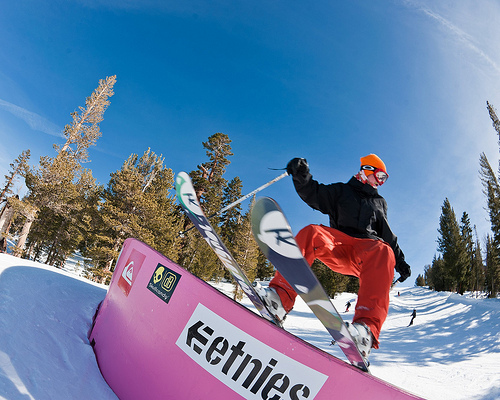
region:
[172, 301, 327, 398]
Advertising on the slopes.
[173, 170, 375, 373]
Two skis belonging to skier.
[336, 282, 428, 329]
Other skiers behind the skier.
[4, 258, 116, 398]
Shadow of the pink object.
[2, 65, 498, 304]
Trees in the background.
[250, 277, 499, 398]
Shadow of the trees.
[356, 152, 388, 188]
Ski hat on the skier.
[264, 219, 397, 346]
Red snow pants on the skier.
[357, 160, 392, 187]
Ski goggles on the skier.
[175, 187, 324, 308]
Brand of the skis on the bottom.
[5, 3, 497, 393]
a scene outside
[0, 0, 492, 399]
a scene during the day time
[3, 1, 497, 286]
a sky with some clouds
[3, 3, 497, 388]
a scene on the slopes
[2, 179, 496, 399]
snow on the ground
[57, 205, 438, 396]
a purple ramp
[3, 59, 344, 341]
some trees in the background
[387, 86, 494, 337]
some green trees in the distance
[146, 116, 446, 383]
a person skiing on a ramp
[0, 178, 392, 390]
a ramp on the snow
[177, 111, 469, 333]
a person holding ski poles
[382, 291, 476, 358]
ground coveredin sno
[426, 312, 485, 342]
ground covered in white snow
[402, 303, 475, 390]
snow covering the ground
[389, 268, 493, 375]
white snow covering the ground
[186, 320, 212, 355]
black letter on wall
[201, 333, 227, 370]
black letter on wall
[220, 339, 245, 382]
black letter on wall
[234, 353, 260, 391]
black letter on wall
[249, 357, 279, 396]
black letter on wall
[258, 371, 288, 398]
black letter on wall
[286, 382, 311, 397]
black letter on wall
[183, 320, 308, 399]
black letters on wall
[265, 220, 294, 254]
black letter on ski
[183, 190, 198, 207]
black letter on ski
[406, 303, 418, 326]
Person skiing down the slope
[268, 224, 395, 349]
Man wearing red ski pants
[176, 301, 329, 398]
Logo on side of pink wall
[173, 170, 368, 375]
Image reflecting on bottom of skis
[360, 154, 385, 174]
Orange hat on man's head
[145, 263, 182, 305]
Black and gold logo on side of wall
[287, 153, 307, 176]
Black glove on man's hand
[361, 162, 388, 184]
Red goggles with black strap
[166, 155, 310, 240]
Ski pole in man's hand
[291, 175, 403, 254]
Men's black ski coat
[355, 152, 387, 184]
the skier is wearing goggles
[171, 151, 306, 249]
the skier is holding a ski pole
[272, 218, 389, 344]
the skier is wearing orange pants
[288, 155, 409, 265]
the skier is wearing a black jacket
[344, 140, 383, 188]
skier has orange hat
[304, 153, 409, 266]
skier has black jacket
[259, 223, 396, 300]
skier has orange pants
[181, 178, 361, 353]
black and white skis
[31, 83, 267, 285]
tall and green trees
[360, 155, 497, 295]
pine trees behind skier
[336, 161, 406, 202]
red and silver goggles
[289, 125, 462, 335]
skier has black gloves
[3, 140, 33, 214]
a tree in a field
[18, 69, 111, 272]
a tree in a field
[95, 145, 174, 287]
a tree in a field